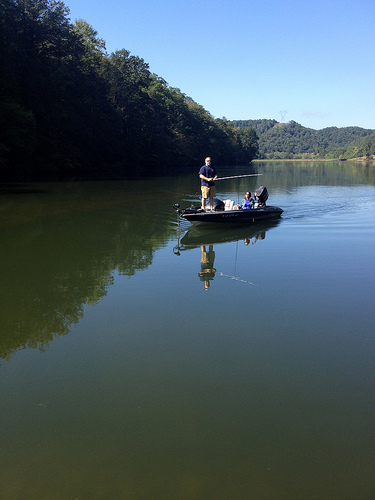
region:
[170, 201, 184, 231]
Trolling motor on front of boat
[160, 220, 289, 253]
Boat reflection in water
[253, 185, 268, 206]
Black boat outboard motor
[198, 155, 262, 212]
Man fishing from boat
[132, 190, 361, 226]
Boat wake in water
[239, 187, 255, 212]
Woman seated in boat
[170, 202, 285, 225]
Fishing boat in water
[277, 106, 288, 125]
Large metal power utility pole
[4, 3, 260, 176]
Leaf covered trees along shore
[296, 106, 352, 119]
Wispy clouds in sky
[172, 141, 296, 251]
the man is fishing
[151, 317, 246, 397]
the water is murky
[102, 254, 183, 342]
the water is murky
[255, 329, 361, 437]
the water is murky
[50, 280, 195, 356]
the water is murky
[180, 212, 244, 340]
a reflection of the man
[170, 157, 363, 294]
a man fishing from a boat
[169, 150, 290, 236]
a man and woman in a boat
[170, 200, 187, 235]
an electric boat engine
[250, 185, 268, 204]
a gas powered boat engine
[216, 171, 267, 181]
a white fishing pole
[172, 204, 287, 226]
a fishing boat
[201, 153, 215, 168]
a man wearing sunglasses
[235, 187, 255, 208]
a woman wearing sunglasses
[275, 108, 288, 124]
a power-line tower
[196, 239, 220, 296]
the reflection of a man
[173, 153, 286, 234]
Man fishing on boat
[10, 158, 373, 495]
Calm green water with no waves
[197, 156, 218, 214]
Man in blue shirt and tan shorts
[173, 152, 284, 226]
Man and woman riding in boat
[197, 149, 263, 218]
Man holding a fishing pole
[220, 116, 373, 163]
Hills covered with trees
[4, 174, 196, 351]
The reflection of trees on water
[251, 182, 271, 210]
Small black motor lifted slightly up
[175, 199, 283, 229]
Small black and white boat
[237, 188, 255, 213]
Woman wearing blue shirt and sunglasses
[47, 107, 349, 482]
The people are doing some fishing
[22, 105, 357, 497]
The people are trying to catch fish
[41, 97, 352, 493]
The people are in a small boat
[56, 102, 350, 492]
The people are in a big Lake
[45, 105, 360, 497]
The person is using a fishing pole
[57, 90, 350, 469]
The boat has an outboard motor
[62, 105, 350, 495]
The boat was designed for fishing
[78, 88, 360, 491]
A couple is enjoying the lake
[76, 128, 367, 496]
Two people are enjoying their day off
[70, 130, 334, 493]
The people are enjoying their day